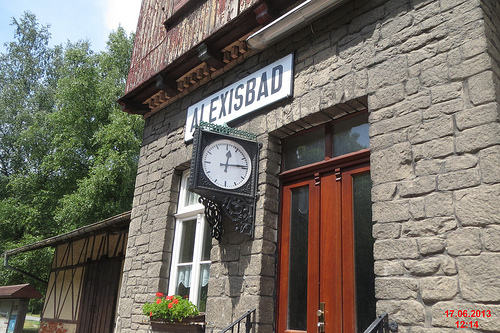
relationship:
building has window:
[114, 0, 499, 332] [161, 162, 208, 318]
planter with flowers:
[146, 313, 205, 331] [141, 291, 198, 322]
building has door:
[3, 209, 133, 332] [74, 255, 124, 332]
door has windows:
[274, 108, 377, 332] [287, 169, 373, 332]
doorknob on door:
[317, 300, 325, 331] [274, 108, 377, 332]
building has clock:
[114, 0, 499, 332] [201, 139, 252, 187]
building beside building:
[3, 209, 133, 332] [114, 0, 499, 332]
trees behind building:
[0, 8, 145, 315] [114, 0, 499, 332]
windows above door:
[279, 108, 369, 175] [274, 108, 377, 332]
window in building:
[161, 162, 208, 318] [114, 0, 499, 332]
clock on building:
[201, 139, 252, 187] [114, 0, 499, 332]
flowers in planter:
[141, 291, 198, 322] [146, 313, 205, 331]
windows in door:
[287, 169, 373, 332] [274, 108, 377, 332]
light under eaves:
[247, 0, 341, 50] [116, 0, 300, 120]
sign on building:
[184, 50, 293, 142] [114, 0, 499, 332]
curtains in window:
[177, 265, 209, 287] [161, 162, 208, 318]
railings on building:
[217, 306, 389, 332] [114, 0, 499, 332]